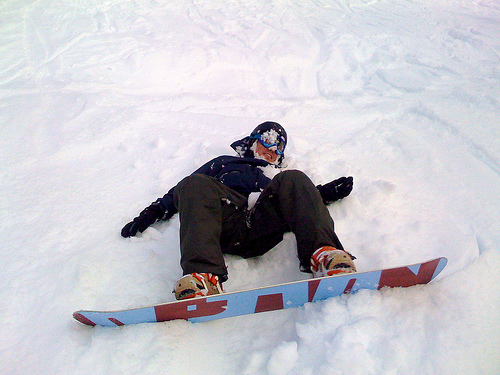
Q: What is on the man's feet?
A: Boots.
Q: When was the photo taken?
A: Daytime.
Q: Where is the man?
A: In the snow.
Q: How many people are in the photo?
A: One.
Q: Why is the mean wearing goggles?
A: To protect his eyes.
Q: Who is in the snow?
A: The man.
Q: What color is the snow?
A: White.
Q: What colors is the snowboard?
A: Red and Blue.